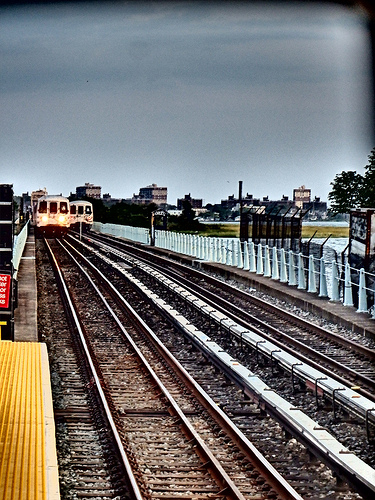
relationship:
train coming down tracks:
[35, 198, 70, 236] [41, 234, 86, 324]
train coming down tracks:
[69, 200, 94, 232] [85, 232, 138, 253]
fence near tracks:
[99, 220, 364, 310] [177, 262, 363, 384]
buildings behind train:
[75, 175, 328, 226] [33, 193, 70, 230]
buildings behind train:
[75, 175, 328, 226] [70, 199, 95, 228]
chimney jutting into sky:
[238, 181, 243, 200] [202, 123, 281, 180]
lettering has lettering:
[0, 282, 8, 286] [0, 282, 8, 286]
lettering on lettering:
[0, 282, 8, 286] [0, 282, 8, 286]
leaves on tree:
[343, 178, 353, 189] [326, 145, 375, 221]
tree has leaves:
[326, 145, 375, 221] [343, 178, 353, 189]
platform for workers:
[13, 227, 38, 345] [3, 236, 45, 338]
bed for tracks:
[3, 207, 15, 253] [60, 229, 327, 458]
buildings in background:
[75, 175, 328, 226] [29, 182, 306, 201]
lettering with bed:
[0, 282, 8, 286] [66, 268, 279, 389]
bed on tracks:
[66, 268, 279, 389] [110, 318, 246, 475]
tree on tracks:
[324, 165, 362, 205] [67, 249, 227, 446]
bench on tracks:
[1, 272, 11, 314] [83, 254, 297, 450]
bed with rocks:
[66, 268, 279, 389] [204, 370, 255, 429]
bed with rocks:
[66, 268, 279, 389] [228, 387, 266, 425]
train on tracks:
[33, 192, 71, 238] [105, 307, 359, 496]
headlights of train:
[41, 214, 67, 224] [31, 190, 99, 239]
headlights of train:
[41, 214, 67, 224] [33, 188, 97, 238]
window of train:
[30, 186, 99, 241] [35, 192, 96, 237]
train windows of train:
[37, 199, 69, 214] [31, 190, 99, 239]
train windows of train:
[37, 199, 69, 214] [32, 188, 105, 242]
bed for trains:
[66, 268, 279, 389] [30, 188, 97, 243]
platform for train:
[7, 178, 45, 345] [27, 193, 102, 237]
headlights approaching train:
[37, 212, 71, 225] [31, 190, 99, 239]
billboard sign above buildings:
[290, 188, 311, 200] [75, 175, 328, 226]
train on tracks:
[33, 192, 71, 238] [41, 234, 292, 486]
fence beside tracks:
[194, 237, 364, 284] [50, 243, 295, 479]